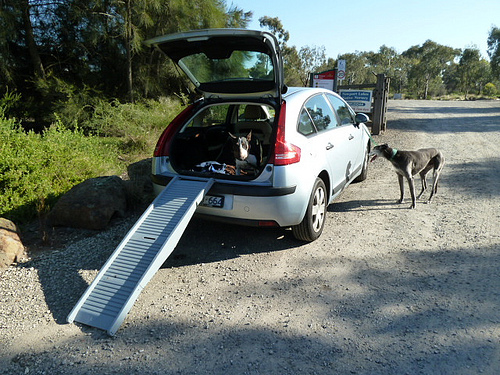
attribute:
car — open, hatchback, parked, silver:
[140, 23, 378, 253]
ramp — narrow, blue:
[55, 169, 216, 344]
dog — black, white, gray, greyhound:
[368, 141, 449, 209]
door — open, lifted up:
[139, 23, 288, 100]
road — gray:
[363, 104, 490, 374]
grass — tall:
[6, 96, 141, 220]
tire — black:
[298, 173, 332, 246]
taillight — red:
[270, 135, 304, 168]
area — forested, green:
[6, 9, 146, 192]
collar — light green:
[388, 147, 398, 165]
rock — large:
[44, 171, 127, 229]